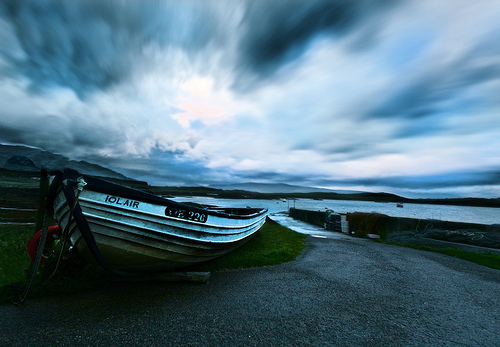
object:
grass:
[174, 212, 313, 268]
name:
[104, 195, 139, 209]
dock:
[251, 206, 397, 234]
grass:
[2, 171, 310, 278]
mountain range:
[1, 139, 146, 185]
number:
[165, 204, 209, 223]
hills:
[0, 141, 500, 280]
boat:
[0, 140, 500, 284]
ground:
[206, 64, 423, 151]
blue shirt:
[409, 205, 500, 226]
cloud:
[220, 0, 370, 94]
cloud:
[4, 1, 19, 18]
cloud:
[89, 64, 119, 91]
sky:
[0, 0, 498, 147]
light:
[27, 223, 67, 265]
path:
[0, 209, 500, 347]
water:
[160, 191, 497, 241]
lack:
[262, 183, 357, 228]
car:
[0, 158, 110, 275]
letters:
[104, 195, 139, 209]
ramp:
[271, 213, 365, 238]